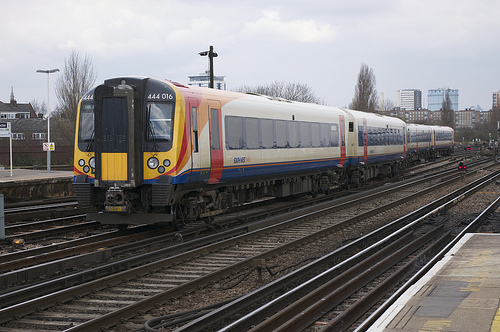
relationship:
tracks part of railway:
[295, 205, 450, 271] [3, 178, 497, 326]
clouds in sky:
[242, 14, 338, 64] [2, 14, 497, 142]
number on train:
[144, 90, 174, 100] [67, 65, 467, 222]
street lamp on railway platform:
[32, 66, 62, 173] [2, 160, 74, 210]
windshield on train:
[144, 99, 174, 141] [67, 65, 467, 222]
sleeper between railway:
[141, 272, 189, 284] [0, 157, 490, 332]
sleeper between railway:
[111, 284, 164, 292] [0, 157, 490, 332]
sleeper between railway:
[38, 307, 100, 322] [0, 157, 490, 332]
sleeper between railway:
[230, 246, 270, 251] [0, 157, 490, 332]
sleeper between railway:
[203, 252, 248, 262] [0, 157, 490, 332]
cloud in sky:
[237, 7, 334, 50] [2, 0, 497, 42]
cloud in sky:
[104, 7, 164, 41] [2, 0, 497, 42]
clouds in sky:
[317, 10, 447, 61] [1, 3, 496, 89]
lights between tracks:
[454, 159, 468, 181] [0, 149, 497, 329]